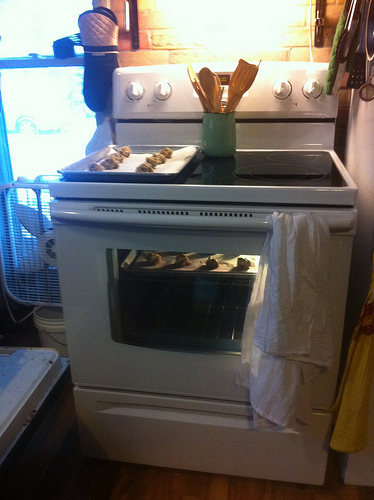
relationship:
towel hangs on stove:
[231, 208, 337, 434] [59, 65, 356, 488]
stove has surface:
[59, 65, 356, 488] [58, 149, 350, 189]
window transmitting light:
[0, 1, 118, 283] [4, 8, 122, 250]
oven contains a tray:
[49, 197, 361, 417] [120, 247, 263, 280]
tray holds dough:
[120, 247, 263, 280] [144, 249, 253, 272]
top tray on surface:
[54, 143, 205, 184] [58, 149, 350, 189]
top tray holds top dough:
[54, 143, 205, 184] [86, 144, 174, 176]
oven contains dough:
[49, 197, 361, 417] [144, 249, 253, 272]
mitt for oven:
[75, 6, 122, 115] [49, 197, 361, 417]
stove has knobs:
[59, 65, 356, 488] [124, 78, 325, 103]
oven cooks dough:
[49, 197, 361, 417] [144, 249, 253, 272]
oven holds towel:
[49, 197, 361, 417] [231, 208, 337, 434]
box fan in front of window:
[0, 173, 66, 309] [0, 1, 118, 283]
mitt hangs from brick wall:
[75, 6, 122, 115] [93, 0, 354, 168]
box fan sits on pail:
[0, 173, 66, 309] [30, 301, 71, 360]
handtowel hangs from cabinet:
[326, 274, 374, 456] [337, 1, 373, 489]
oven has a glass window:
[49, 197, 361, 417] [102, 245, 262, 357]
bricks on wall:
[140, 12, 181, 50] [136, 1, 315, 46]